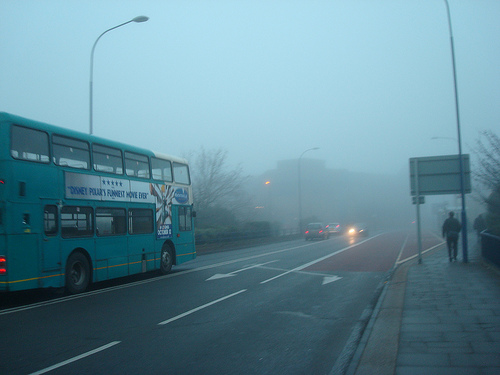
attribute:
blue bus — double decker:
[2, 108, 258, 280]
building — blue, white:
[191, 162, 413, 245]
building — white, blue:
[269, 160, 403, 231]